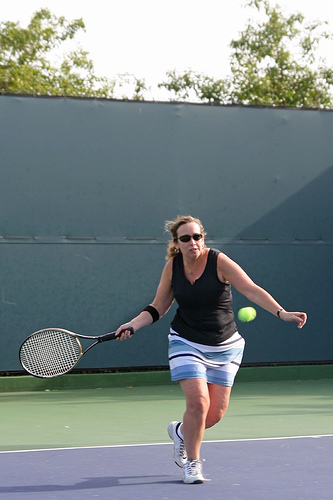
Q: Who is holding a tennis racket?
A: Tennis player.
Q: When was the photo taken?
A: Daytime.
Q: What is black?
A: Player's shirt.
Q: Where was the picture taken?
A: At a tennis court.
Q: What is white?
A: Sneakers.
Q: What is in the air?
A: Tennis ball.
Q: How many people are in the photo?
A: One.